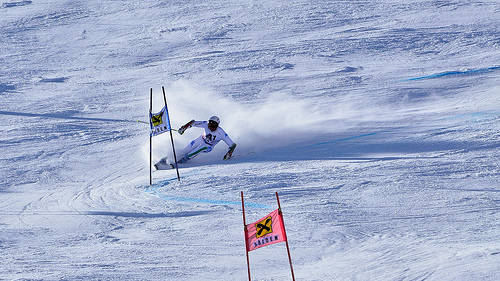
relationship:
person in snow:
[154, 114, 237, 171] [1, 1, 500, 280]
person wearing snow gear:
[154, 114, 237, 171] [169, 121, 236, 161]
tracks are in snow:
[19, 161, 147, 228] [1, 1, 500, 280]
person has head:
[154, 114, 237, 171] [208, 114, 221, 131]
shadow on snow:
[0, 211, 217, 218] [1, 1, 500, 280]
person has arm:
[154, 114, 237, 171] [220, 129, 235, 149]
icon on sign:
[152, 113, 164, 128] [149, 85, 179, 188]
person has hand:
[154, 114, 237, 171] [223, 149, 233, 157]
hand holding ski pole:
[178, 127, 185, 135] [140, 120, 179, 134]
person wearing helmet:
[154, 114, 237, 171] [209, 114, 222, 123]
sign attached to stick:
[149, 85, 179, 188] [149, 88, 152, 185]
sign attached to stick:
[149, 85, 179, 188] [161, 86, 179, 178]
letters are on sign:
[253, 234, 279, 248] [241, 192, 296, 281]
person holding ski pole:
[154, 114, 237, 171] [140, 120, 179, 134]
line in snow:
[151, 187, 277, 211] [1, 1, 500, 280]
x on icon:
[258, 219, 271, 235] [254, 217, 273, 238]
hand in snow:
[223, 149, 233, 157] [1, 1, 500, 280]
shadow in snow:
[179, 136, 497, 167] [1, 1, 500, 280]